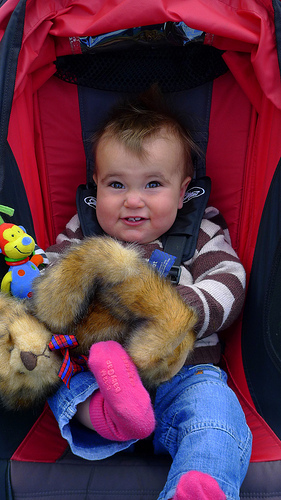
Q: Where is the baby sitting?
A: In stroller.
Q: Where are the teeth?
A: In mouth.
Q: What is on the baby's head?
A: Hair.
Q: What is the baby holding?
A: Bear.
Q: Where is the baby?
A: Sitting in Stroller.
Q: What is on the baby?
A: Striped sweater.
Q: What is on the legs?
A: Blue jeans.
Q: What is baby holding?
A: Bear.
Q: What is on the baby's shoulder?
A: Two straps.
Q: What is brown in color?
A: The bear.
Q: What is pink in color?
A: Socks.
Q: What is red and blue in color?
A: A ribbon.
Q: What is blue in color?
A: Jeans.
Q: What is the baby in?
A: A stroller.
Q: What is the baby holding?
A: A stuffed animal.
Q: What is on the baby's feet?
A: Socks.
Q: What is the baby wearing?
A: A sweater.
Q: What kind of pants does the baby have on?
A: Jeans.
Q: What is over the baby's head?
A: Stroller canopy.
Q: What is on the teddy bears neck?
A: A bow.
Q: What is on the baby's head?
A: Hair.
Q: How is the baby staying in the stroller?
A: Strapped in.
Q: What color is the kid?
A: White.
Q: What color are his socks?
A: Pink.